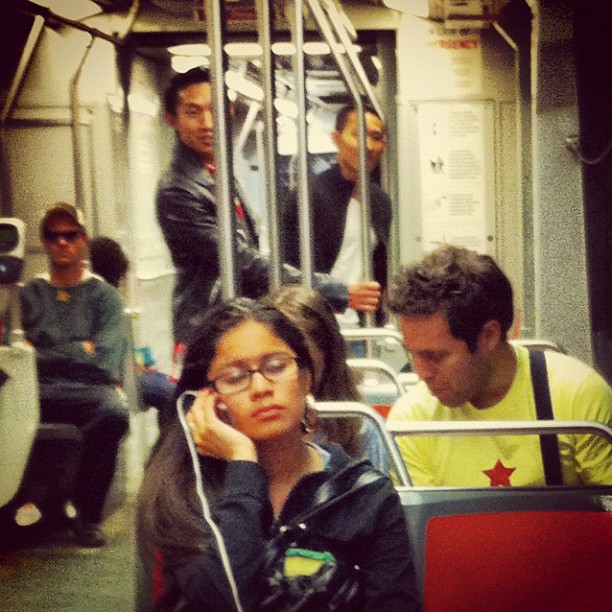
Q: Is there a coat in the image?
A: Yes, there is a coat.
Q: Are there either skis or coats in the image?
A: Yes, there is a coat.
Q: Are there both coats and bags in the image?
A: Yes, there are both a coat and a bag.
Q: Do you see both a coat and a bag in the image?
A: Yes, there are both a coat and a bag.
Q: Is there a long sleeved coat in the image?
A: Yes, there is a long sleeved coat.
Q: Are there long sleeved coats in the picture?
A: Yes, there is a long sleeved coat.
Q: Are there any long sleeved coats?
A: Yes, there is a long sleeved coat.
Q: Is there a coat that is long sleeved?
A: Yes, there is a coat that is long sleeved.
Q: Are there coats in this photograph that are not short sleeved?
A: Yes, there is a long sleeved coat.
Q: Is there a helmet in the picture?
A: No, there are no helmets.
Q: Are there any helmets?
A: No, there are no helmets.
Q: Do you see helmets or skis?
A: No, there are no helmets or skis.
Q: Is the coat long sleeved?
A: Yes, the coat is long sleeved.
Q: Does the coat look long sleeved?
A: Yes, the coat is long sleeved.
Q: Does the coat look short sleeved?
A: No, the coat is long sleeved.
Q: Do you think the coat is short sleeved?
A: No, the coat is long sleeved.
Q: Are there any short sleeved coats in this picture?
A: No, there is a coat but it is long sleeved.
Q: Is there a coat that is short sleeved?
A: No, there is a coat but it is long sleeved.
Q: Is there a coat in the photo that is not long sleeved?
A: No, there is a coat but it is long sleeved.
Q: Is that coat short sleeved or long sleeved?
A: The coat is long sleeved.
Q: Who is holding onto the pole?
A: The man is holding onto the pole.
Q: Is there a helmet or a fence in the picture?
A: No, there are no fences or helmets.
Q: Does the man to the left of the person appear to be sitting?
A: Yes, the man is sitting.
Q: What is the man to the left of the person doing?
A: The man is sitting.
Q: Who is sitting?
A: The man is sitting.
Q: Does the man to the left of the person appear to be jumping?
A: No, the man is sitting.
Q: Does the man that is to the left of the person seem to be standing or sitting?
A: The man is sitting.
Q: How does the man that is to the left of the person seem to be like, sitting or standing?
A: The man is sitting.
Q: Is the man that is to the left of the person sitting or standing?
A: The man is sitting.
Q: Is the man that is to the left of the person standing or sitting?
A: The man is sitting.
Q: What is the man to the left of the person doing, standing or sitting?
A: The man is sitting.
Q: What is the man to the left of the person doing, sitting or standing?
A: The man is sitting.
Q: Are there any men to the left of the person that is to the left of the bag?
A: Yes, there is a man to the left of the person.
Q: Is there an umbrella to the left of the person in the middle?
A: No, there is a man to the left of the person.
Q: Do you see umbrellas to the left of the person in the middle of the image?
A: No, there is a man to the left of the person.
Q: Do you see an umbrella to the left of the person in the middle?
A: No, there is a man to the left of the person.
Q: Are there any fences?
A: No, there are no fences.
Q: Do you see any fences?
A: No, there are no fences.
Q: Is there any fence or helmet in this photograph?
A: No, there are no fences or helmets.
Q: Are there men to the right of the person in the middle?
A: Yes, there is a man to the right of the person.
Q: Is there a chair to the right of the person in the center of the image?
A: No, there is a man to the right of the person.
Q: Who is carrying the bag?
A: The man is carrying the bag.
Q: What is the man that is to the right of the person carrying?
A: The man is carrying a bag.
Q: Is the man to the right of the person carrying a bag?
A: Yes, the man is carrying a bag.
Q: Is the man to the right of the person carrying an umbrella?
A: No, the man is carrying a bag.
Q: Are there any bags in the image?
A: Yes, there is a bag.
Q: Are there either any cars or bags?
A: Yes, there is a bag.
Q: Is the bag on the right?
A: Yes, the bag is on the right of the image.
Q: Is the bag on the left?
A: No, the bag is on the right of the image.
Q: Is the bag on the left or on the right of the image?
A: The bag is on the right of the image.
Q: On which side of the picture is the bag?
A: The bag is on the right of the image.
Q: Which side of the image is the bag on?
A: The bag is on the right of the image.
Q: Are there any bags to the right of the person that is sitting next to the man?
A: Yes, there is a bag to the right of the person.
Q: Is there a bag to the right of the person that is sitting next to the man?
A: Yes, there is a bag to the right of the person.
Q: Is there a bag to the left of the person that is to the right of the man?
A: No, the bag is to the right of the person.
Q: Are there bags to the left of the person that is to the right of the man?
A: No, the bag is to the right of the person.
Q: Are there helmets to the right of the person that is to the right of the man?
A: No, there is a bag to the right of the person.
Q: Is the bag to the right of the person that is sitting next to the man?
A: Yes, the bag is to the right of the person.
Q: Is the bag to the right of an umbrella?
A: No, the bag is to the right of the person.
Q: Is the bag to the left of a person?
A: No, the bag is to the right of a person.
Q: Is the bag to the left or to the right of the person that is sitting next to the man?
A: The bag is to the right of the person.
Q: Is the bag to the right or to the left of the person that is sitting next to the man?
A: The bag is to the right of the person.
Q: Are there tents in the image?
A: No, there are no tents.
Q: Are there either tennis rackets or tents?
A: No, there are no tents or tennis rackets.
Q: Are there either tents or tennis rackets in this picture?
A: No, there are no tents or tennis rackets.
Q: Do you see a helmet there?
A: No, there are no helmets.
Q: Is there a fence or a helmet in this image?
A: No, there are no helmets or fences.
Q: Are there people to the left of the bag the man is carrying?
A: Yes, there is a person to the left of the bag.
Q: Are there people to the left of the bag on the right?
A: Yes, there is a person to the left of the bag.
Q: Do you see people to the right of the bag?
A: No, the person is to the left of the bag.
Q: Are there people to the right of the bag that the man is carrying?
A: No, the person is to the left of the bag.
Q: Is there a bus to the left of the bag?
A: No, there is a person to the left of the bag.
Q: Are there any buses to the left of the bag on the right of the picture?
A: No, there is a person to the left of the bag.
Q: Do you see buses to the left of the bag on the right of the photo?
A: No, there is a person to the left of the bag.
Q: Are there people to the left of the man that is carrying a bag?
A: Yes, there is a person to the left of the man.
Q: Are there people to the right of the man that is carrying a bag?
A: No, the person is to the left of the man.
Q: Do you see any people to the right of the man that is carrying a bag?
A: No, the person is to the left of the man.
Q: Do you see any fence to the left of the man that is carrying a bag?
A: No, there is a person to the left of the man.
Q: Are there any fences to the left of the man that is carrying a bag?
A: No, there is a person to the left of the man.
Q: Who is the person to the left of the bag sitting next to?
A: The person is sitting next to the man.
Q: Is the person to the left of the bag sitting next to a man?
A: Yes, the person is sitting next to a man.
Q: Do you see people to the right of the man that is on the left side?
A: Yes, there is a person to the right of the man.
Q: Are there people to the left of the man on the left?
A: No, the person is to the right of the man.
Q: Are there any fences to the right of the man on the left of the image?
A: No, there is a person to the right of the man.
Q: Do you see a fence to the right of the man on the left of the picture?
A: No, there is a person to the right of the man.